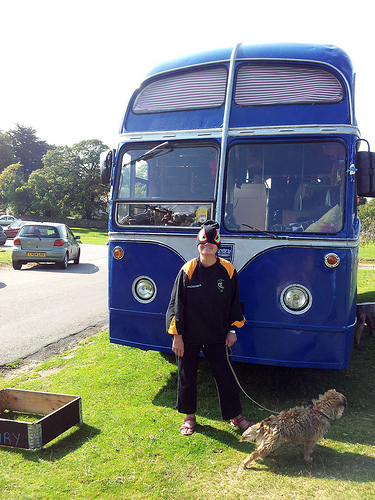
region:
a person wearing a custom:
[153, 214, 356, 477]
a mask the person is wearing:
[193, 218, 221, 248]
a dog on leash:
[237, 385, 348, 476]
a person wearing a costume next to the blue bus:
[96, 35, 368, 474]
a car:
[9, 219, 84, 276]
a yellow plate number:
[21, 249, 47, 259]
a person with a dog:
[161, 214, 349, 474]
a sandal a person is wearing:
[175, 411, 199, 439]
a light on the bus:
[274, 279, 314, 319]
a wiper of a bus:
[121, 139, 176, 166]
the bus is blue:
[122, 47, 351, 356]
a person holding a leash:
[151, 198, 340, 487]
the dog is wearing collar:
[245, 367, 347, 496]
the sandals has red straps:
[164, 392, 274, 458]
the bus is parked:
[93, 135, 343, 439]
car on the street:
[1, 205, 79, 311]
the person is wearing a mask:
[182, 203, 221, 277]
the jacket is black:
[154, 256, 270, 349]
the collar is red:
[307, 398, 336, 428]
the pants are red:
[174, 277, 267, 470]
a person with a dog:
[149, 204, 353, 485]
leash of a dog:
[225, 347, 302, 425]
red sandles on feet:
[176, 412, 264, 447]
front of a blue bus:
[85, 138, 368, 386]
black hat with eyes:
[192, 215, 239, 248]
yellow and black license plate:
[23, 249, 54, 260]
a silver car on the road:
[12, 204, 79, 275]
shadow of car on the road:
[34, 256, 102, 283]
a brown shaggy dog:
[246, 377, 366, 472]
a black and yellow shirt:
[159, 251, 257, 338]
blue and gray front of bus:
[105, 43, 361, 368]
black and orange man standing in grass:
[159, 222, 246, 436]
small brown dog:
[236, 379, 341, 465]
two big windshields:
[108, 132, 348, 241]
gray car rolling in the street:
[9, 216, 79, 267]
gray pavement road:
[0, 233, 131, 354]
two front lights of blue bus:
[126, 273, 309, 318]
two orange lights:
[108, 236, 337, 266]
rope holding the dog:
[217, 342, 287, 419]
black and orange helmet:
[195, 223, 221, 242]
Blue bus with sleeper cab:
[103, 42, 360, 234]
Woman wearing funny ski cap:
[185, 216, 227, 262]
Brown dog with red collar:
[236, 386, 351, 471]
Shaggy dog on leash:
[233, 385, 353, 471]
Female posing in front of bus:
[104, 45, 359, 374]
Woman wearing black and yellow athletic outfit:
[163, 218, 245, 421]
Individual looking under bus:
[353, 298, 374, 355]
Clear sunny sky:
[4, 5, 115, 129]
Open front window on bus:
[115, 147, 214, 225]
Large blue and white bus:
[237, 43, 351, 370]